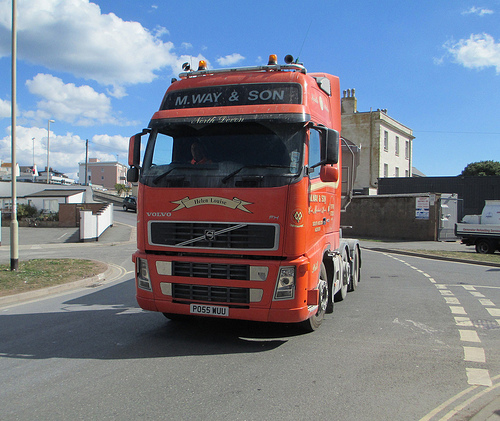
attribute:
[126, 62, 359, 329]
truck — red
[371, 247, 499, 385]
lines — white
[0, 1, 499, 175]
sky — blue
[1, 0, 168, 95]
clouds — white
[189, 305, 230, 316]
license plate — white